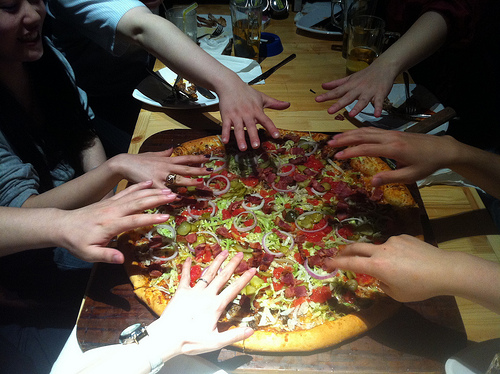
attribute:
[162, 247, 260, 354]
hands — reaching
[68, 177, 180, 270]
hands — reaching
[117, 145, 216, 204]
hands — reaching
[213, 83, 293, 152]
hands — reaching, customers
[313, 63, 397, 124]
hands — reaching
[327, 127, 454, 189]
hands — reaching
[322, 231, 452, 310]
hands — reaching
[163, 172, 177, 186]
ring — large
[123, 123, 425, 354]
pizza — golden, round, lots of toppings, many toppings, supreme, large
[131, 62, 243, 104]
plates — white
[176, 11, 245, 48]
plates — white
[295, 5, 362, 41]
plates — white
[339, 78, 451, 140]
plates — white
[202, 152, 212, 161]
fingernails — black, painted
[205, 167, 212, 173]
fingernails — black, painted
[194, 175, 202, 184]
fingernails — red, painted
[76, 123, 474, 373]
tray — brwon, brown, wooden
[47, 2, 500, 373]
table — wooden, light colored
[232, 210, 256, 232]
onion — ringed, red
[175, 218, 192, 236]
pickel — green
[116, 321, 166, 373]
watch — white